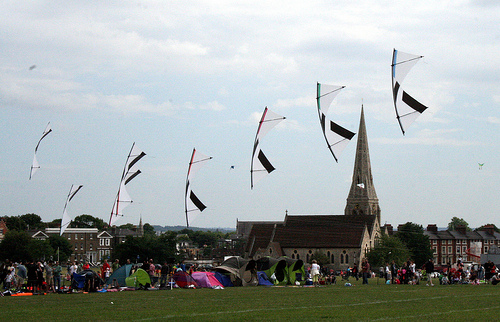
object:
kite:
[27, 121, 53, 181]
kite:
[57, 183, 84, 237]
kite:
[107, 141, 148, 227]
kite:
[181, 147, 212, 226]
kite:
[249, 106, 287, 189]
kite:
[312, 81, 356, 167]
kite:
[389, 49, 428, 137]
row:
[25, 48, 430, 237]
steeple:
[342, 99, 380, 216]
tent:
[258, 253, 289, 286]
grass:
[0, 284, 499, 322]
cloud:
[366, 127, 486, 146]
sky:
[0, 0, 498, 225]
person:
[35, 259, 44, 293]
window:
[337, 249, 350, 264]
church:
[229, 208, 389, 275]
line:
[137, 290, 499, 322]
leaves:
[443, 216, 474, 232]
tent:
[187, 269, 225, 290]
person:
[356, 255, 374, 285]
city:
[3, 207, 499, 321]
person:
[100, 255, 113, 278]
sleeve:
[101, 260, 112, 269]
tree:
[364, 232, 414, 285]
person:
[306, 259, 321, 289]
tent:
[123, 268, 152, 290]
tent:
[276, 256, 298, 284]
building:
[409, 222, 499, 271]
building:
[43, 226, 114, 265]